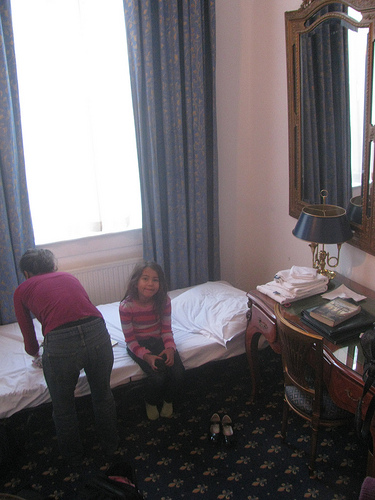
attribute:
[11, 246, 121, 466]
lady — here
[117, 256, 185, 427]
girl — here, young, sitting, looking, small, seated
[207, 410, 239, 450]
pair — here, shoes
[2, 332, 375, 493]
floor — here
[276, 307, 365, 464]
chair — here, elegant, desk, wooden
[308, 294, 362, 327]
book — here, laying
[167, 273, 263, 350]
pillow — here, white, sitting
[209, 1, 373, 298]
wall — here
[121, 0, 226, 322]
curtain — here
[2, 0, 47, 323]
curtain — here, reflecting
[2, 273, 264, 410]
sheets — white, bed, set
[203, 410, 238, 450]
shoes — polished, black, sitting, off, girl's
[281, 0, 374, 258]
mirror — wooden, large, hanging, wall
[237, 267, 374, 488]
desk — made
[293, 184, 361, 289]
lamp — blue, gold, here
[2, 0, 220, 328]
curtains — blue, large, yellow, wall to ceiling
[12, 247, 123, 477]
woman — bending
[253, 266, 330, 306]
towels — white, bath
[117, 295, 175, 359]
shirt — striped, girl's, pink, woman's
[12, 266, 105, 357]
shirt — pink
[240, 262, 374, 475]
table — ornate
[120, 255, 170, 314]
hair — brow, girl's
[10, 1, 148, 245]
light — shining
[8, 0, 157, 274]
window — closaed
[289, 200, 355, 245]
shade — green, lamp's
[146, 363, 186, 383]
knees — bent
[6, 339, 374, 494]
mat — black